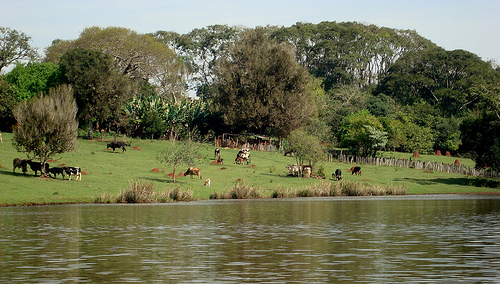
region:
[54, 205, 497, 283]
ripples on the water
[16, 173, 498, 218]
the shoreline in the country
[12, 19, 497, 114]
trees in the background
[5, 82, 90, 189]
Holsteins stand under a tree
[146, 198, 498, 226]
reflections of the long grass along the water edge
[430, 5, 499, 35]
clear blue sky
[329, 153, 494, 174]
a wooden fence to separate the pasture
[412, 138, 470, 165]
piles of reddish colored silage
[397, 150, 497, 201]
a shadow of a tree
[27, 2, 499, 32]
a hazy blue sky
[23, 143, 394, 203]
The animals are in the pasture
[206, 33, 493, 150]
There are trees in the background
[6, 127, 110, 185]
The cows are under the tree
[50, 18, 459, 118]
The sky is blue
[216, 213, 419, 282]
The water is calm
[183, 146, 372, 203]
The animals are eating grass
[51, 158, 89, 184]
The cow is black and white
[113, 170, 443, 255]
There are no ducks in the water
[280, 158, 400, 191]
These animals are near a tree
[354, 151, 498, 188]
There is a fence back here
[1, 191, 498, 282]
the water is calm and green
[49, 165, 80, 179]
a black and white cow under a tree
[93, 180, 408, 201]
grass growing next to the water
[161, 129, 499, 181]
a wooden fence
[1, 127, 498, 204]
cows in a grassy green field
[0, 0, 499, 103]
the sky is blue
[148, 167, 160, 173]
small brown piles on the grass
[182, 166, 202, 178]
a brown and white cow is grazing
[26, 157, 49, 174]
a black cow under a tree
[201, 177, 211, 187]
a small brown and white calf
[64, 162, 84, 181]
a cow out in the field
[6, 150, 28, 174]
a cow out in the field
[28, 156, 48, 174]
a cow out in the field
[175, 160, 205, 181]
a cow out in the field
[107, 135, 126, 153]
a cow out in the field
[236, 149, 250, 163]
a cow out in the field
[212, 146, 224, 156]
a cow out in the field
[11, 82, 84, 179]
a tree out in the field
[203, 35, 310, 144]
a tree out in the field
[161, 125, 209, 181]
a tree out in the field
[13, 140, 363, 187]
cows are grazing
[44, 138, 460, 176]
red haystacks in the fields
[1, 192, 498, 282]
pond in front of cows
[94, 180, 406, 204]
tall grass behind pond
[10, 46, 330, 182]
short trees in field with the cows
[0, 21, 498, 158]
tall trees in background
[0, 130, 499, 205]
short grass in two fields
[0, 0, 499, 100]
sky is blue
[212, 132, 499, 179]
wooden fence next to the fields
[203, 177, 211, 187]
small calf near pond